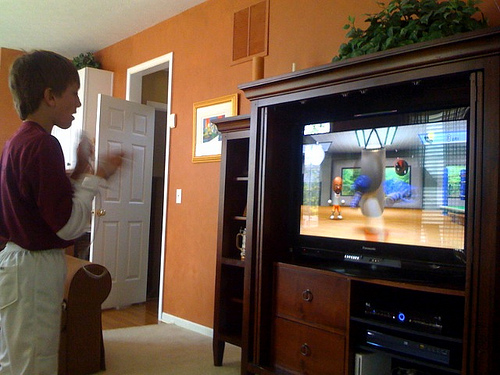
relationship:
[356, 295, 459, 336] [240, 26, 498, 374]
dvd player on stand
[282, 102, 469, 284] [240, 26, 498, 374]
tv on stand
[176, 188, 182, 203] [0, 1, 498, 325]
light switch on wall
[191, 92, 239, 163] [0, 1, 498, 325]
picture on wall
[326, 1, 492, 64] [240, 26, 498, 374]
plant on stand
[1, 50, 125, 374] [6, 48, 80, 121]
boy with brown hair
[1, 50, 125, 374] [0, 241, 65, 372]
boy wearing long pants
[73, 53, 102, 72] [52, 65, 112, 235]
plant on cabinet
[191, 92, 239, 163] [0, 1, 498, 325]
picture hanging on wall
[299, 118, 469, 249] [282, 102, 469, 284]
video game on tv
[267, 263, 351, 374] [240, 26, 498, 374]
drawers on stand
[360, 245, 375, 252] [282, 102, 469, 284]
name brand of tv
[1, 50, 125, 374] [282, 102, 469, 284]
boy stands in front of tv